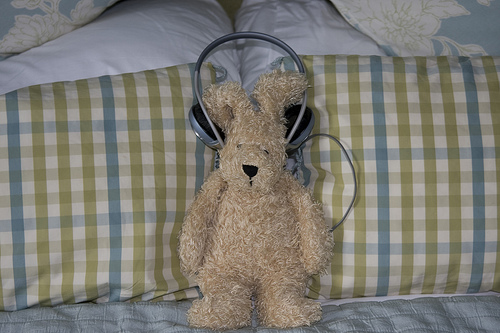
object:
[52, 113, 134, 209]
part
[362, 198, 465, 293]
part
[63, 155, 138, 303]
part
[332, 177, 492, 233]
part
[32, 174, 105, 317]
part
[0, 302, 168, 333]
blanket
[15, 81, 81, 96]
pillow case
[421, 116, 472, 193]
three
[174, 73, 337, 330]
stuffed animals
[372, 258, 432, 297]
long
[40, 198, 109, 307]
long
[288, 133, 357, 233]
lines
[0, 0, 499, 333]
bed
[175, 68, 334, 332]
rabbit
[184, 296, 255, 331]
foot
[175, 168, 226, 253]
arm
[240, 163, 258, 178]
nose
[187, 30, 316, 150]
ear phones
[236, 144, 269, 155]
eyes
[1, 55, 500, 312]
pillows